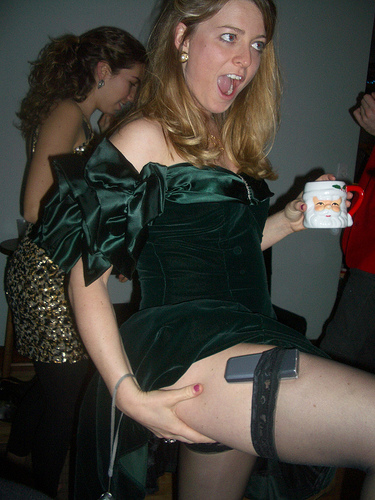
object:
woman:
[34, 0, 374, 499]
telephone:
[222, 344, 304, 385]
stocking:
[251, 345, 371, 467]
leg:
[169, 330, 373, 472]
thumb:
[167, 381, 206, 409]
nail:
[192, 382, 201, 392]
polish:
[193, 382, 201, 396]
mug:
[300, 177, 365, 232]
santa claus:
[299, 178, 348, 231]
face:
[190, 1, 263, 113]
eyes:
[250, 36, 268, 52]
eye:
[217, 31, 241, 46]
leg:
[169, 430, 259, 498]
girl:
[5, 19, 149, 498]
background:
[2, 1, 197, 439]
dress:
[30, 128, 340, 499]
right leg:
[141, 326, 375, 473]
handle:
[344, 184, 365, 217]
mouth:
[212, 73, 245, 102]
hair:
[141, 2, 283, 186]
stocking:
[175, 437, 254, 499]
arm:
[60, 127, 139, 389]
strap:
[105, 369, 137, 479]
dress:
[5, 108, 91, 368]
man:
[313, 53, 375, 365]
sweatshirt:
[339, 125, 375, 274]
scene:
[7, 1, 373, 498]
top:
[243, 343, 292, 463]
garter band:
[247, 340, 292, 463]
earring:
[175, 49, 190, 65]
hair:
[11, 19, 150, 164]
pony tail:
[12, 31, 83, 163]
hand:
[123, 381, 218, 448]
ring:
[163, 434, 180, 444]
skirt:
[2, 225, 92, 367]